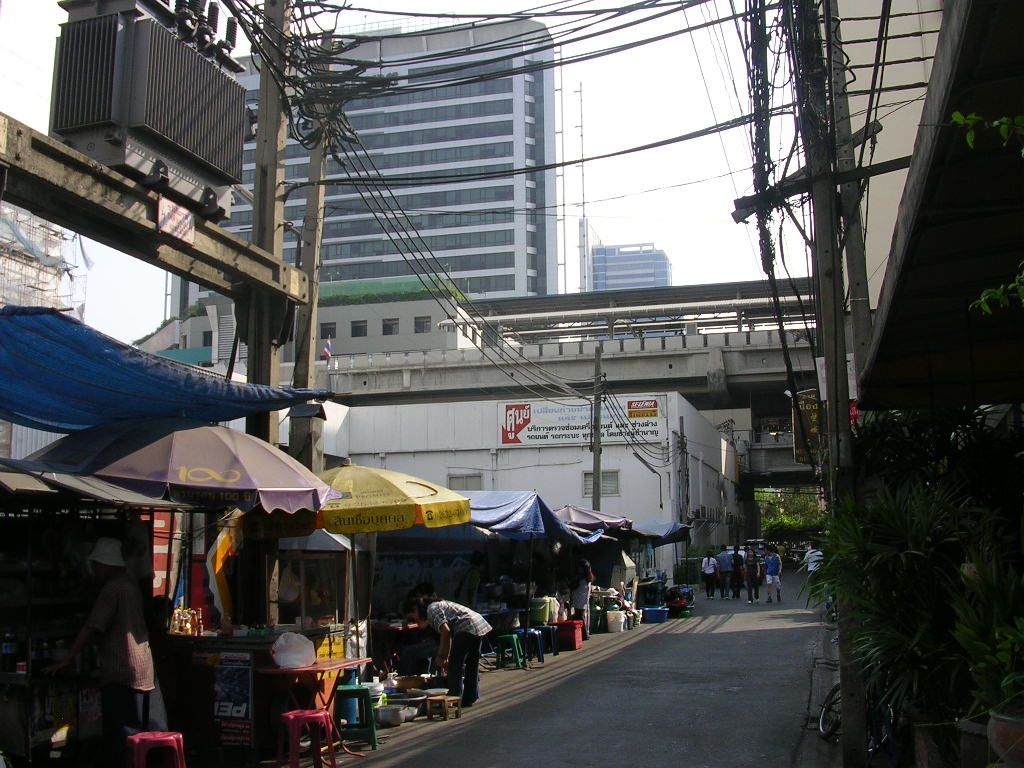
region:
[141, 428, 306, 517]
an umbrella that is purple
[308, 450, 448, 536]
an umbrella that is yellow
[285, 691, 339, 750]
a stool that is red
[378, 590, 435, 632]
the head of a person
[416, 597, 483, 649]
the shirt of a person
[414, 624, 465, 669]
the arm of a person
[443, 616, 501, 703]
the legs of a person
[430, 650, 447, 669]
the hand of a person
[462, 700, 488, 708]
the shoes of a person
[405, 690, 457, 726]
a small brown box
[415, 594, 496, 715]
Woman leaning over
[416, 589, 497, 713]
Woman leaning next to street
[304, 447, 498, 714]
Yellow umbrella over woman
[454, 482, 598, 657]
Blue tent next to street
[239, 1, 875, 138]
Electrical wires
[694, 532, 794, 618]
Group of people on street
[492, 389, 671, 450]
Red and white sign on building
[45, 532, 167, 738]
man wearing a white hat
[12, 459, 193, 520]
awning above the man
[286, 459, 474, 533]
yellow umbrella is open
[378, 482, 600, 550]
blue canopy behind umbrella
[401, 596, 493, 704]
woman is bending over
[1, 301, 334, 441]
blue tarp hanging abpve umbrella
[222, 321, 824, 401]
bridge above the building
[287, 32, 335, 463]
tall wooden utility pole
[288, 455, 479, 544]
yellow patio umbrella with writing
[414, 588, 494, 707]
person in gray shirt and black pants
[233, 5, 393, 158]
electrical wire clumped together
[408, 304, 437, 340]
small square window in white wall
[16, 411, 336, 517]
lavender patio umbrella with yellow pattern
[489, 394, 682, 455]
white banner with two red symbols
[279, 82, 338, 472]
long wooden pole for electricity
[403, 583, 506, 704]
woman bending over table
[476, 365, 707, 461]
banner at side of building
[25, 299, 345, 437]
blue awning over store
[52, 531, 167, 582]
white hat on head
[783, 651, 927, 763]
bike's wheel behind wooden pole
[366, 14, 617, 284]
tall white building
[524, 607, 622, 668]
red basket on the sidewalk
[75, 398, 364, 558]
purple umbrella over awning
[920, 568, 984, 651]
green leaf on the plant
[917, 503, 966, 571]
green leaf on the plant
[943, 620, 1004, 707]
green leaf on the plant